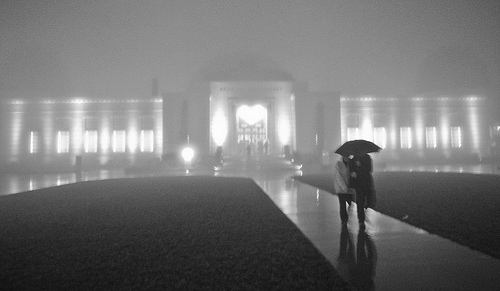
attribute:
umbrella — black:
[336, 137, 381, 158]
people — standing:
[334, 153, 377, 230]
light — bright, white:
[178, 144, 200, 163]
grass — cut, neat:
[52, 183, 284, 281]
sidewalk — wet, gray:
[254, 176, 498, 271]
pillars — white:
[183, 89, 216, 159]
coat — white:
[334, 159, 352, 196]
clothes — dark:
[352, 157, 376, 204]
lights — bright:
[236, 103, 266, 126]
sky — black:
[13, 4, 471, 59]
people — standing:
[246, 140, 270, 156]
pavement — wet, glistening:
[237, 166, 495, 288]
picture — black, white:
[6, 8, 496, 284]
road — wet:
[259, 182, 497, 287]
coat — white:
[335, 159, 356, 194]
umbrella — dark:
[335, 140, 381, 156]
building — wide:
[10, 71, 479, 169]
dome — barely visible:
[0, 40, 77, 97]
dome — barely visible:
[192, 47, 289, 77]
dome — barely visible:
[414, 43, 496, 95]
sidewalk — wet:
[250, 174, 498, 289]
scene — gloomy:
[34, 39, 395, 203]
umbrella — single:
[334, 135, 371, 155]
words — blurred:
[170, 48, 302, 106]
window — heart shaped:
[229, 96, 273, 136]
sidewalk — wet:
[266, 172, 496, 284]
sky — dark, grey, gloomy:
[4, 1, 498, 83]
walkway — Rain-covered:
[279, 174, 403, 287]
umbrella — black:
[332, 135, 385, 155]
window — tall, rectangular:
[25, 127, 39, 155]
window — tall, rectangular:
[54, 128, 71, 155]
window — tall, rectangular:
[81, 129, 100, 153]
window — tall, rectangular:
[111, 128, 128, 154]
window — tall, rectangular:
[137, 127, 155, 154]